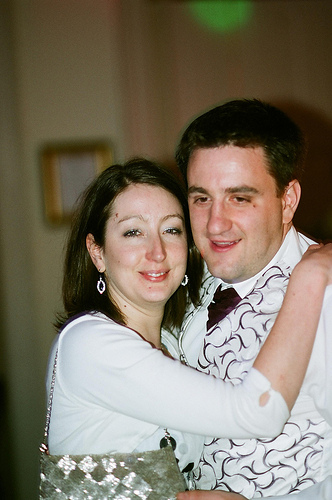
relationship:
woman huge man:
[43, 156, 330, 500] [175, 99, 330, 500]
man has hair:
[175, 99, 330, 500] [176, 101, 301, 197]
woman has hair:
[43, 156, 330, 500] [52, 157, 200, 335]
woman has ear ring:
[43, 156, 330, 500] [96, 274, 106, 293]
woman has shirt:
[43, 156, 330, 500] [44, 311, 289, 479]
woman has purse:
[43, 156, 330, 500] [37, 314, 193, 499]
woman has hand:
[43, 156, 330, 500] [285, 238, 330, 289]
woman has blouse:
[43, 156, 330, 500] [44, 311, 289, 479]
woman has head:
[43, 156, 330, 500] [85, 159, 190, 308]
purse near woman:
[37, 314, 193, 499] [43, 156, 330, 500]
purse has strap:
[37, 314, 193, 499] [41, 314, 109, 454]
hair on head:
[52, 157, 200, 335] [85, 159, 190, 308]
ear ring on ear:
[96, 274, 106, 293] [84, 235, 107, 276]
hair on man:
[176, 101, 301, 197] [175, 99, 330, 500]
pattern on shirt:
[207, 443, 317, 486] [44, 311, 289, 479]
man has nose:
[175, 99, 330, 500] [207, 205, 232, 237]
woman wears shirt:
[43, 156, 330, 500] [44, 311, 289, 479]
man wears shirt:
[175, 99, 330, 500] [182, 231, 329, 497]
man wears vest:
[175, 99, 330, 500] [175, 226, 331, 497]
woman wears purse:
[43, 156, 330, 500] [37, 314, 193, 499]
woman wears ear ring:
[43, 156, 330, 500] [96, 274, 106, 293]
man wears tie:
[175, 99, 330, 500] [208, 284, 239, 330]